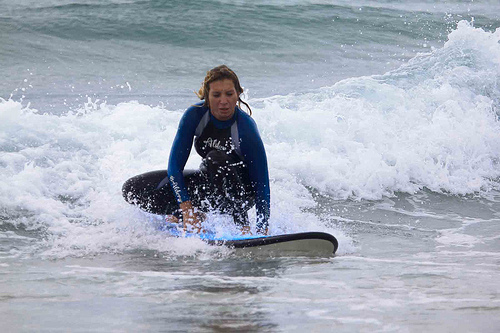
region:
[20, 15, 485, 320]
The person is in the ocean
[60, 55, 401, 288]
A person is on a surfboard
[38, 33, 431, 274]
A person is wearing a wetsuit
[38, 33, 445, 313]
A person is having a great time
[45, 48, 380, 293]
A person is getting very wet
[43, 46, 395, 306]
A person is learning how to surf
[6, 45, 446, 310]
A person is close to the beach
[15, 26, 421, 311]
The person's feet are on a surfboard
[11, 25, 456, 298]
The person is out in the daytime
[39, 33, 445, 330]
A person is enjoying their day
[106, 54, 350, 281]
The woman is on a surfboard.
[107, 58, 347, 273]
The woman is wearing a wetsuit.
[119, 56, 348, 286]
The woman has wet hair.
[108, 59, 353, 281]
The surfboard is in the water.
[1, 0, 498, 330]
The water is splashing.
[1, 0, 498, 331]
The water is wavy.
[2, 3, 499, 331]
The water is assertive.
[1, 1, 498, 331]
The water is agressive.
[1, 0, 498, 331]
The water is lively.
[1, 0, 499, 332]
The water is zealous.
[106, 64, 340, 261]
woman on a surfboard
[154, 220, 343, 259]
blue white and black surfboard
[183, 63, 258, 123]
woman has long hair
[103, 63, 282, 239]
woman is squatting down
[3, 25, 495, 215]
foam of the wave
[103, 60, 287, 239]
woman is wearing a blue and black wet suit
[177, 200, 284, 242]
her hands are touching the surfboard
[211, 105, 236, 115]
the woman's mouth is slightly open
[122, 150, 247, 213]
woman's knees are bent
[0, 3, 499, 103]
wave starting to crest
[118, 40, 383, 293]
Woman on a surfboard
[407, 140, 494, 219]
Small ripple in the water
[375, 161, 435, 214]
Small ripple in the water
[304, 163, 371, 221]
Small ripple in the water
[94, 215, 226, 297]
Small ripple in the water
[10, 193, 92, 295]
Small ripple in the water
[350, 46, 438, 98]
Small ripple in the water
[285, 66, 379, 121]
Small ripple in the water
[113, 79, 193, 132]
Small ripple in the water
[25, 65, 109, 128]
Small ripple in the water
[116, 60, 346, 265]
A woman surfing in the ocean